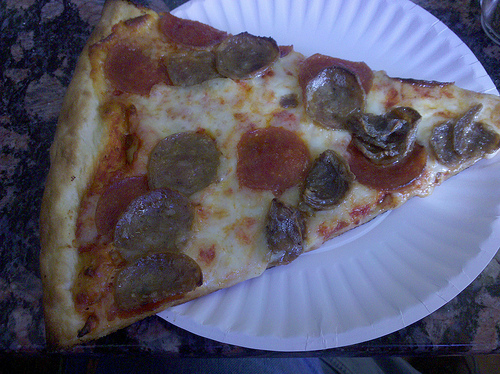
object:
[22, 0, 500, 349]
pizza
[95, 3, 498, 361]
plate